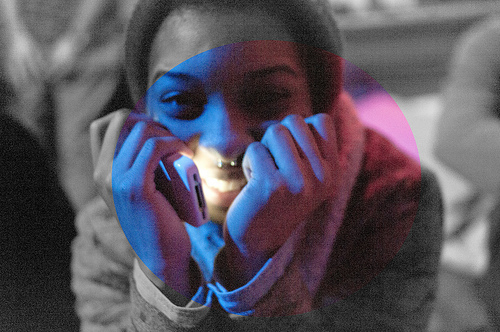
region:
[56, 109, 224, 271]
girl holding pink phone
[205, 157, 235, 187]
small silver nose ring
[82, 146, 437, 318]
girl wearing gray shirt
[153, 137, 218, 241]
small pink smart phone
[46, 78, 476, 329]
girl wearing hooded shirt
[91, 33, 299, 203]
girl with silver nose ring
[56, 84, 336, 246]
girl talking on pink phone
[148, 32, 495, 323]
girl highlighting with pink ring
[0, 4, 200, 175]
people in background of girl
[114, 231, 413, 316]
white shirt under gray shirt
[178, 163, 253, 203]
the girl is smiling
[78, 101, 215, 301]
the girl is holding a phone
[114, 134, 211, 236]
this is a phone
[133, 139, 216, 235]
the phone is white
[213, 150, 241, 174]
the girl has a pierced septum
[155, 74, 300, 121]
these are her eyes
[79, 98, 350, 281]
these are her hands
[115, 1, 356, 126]
the girl is wearing a hat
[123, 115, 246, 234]
the light from the phone is shining on her face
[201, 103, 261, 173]
this is her nose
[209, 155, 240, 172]
THE GIRL HAS A SEPTUM PIERCING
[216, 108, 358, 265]
THIS IS A HAND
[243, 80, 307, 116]
THIS IS AN EYE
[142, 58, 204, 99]
THIS IS AN EYEBROW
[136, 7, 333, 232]
THIS IS A FACE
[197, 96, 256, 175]
THIS IS A NOSE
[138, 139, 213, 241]
THIS IS A PHONE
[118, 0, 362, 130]
THE GIRL IS WEARING A HAT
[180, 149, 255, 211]
THE GIRL IS SMILING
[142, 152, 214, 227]
THE GIRL IS HOLDING A PHONE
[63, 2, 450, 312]
Girl dressed warm is on a cell phone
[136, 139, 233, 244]
Phone is lit up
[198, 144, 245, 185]
Nose is pierced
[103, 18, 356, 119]
Girl wearing a stocking cap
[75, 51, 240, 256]
Girl is holding a cell phone against her cheek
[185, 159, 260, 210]
Girl smiling while on phone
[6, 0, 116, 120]
Person in background is out of focus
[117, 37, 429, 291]
Circle of color in a black and white photo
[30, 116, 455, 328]
Girl is dressed warmly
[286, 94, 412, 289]
Girl is wearing a scarf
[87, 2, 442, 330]
person holding cell phone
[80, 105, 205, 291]
hand holding cell phone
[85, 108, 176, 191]
four fingers on hand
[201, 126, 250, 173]
nose of person holding phone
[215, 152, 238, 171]
nose ring in nose of person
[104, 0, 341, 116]
person wearing black hat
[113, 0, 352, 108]
black hat on person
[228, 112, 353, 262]
left hand of person holding phone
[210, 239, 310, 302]
white shirt sleeve of person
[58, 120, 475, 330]
gray sweater on person holding phone